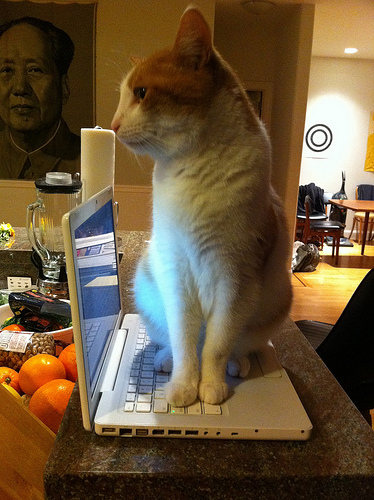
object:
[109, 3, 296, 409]
cat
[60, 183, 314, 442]
laptop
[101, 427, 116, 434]
port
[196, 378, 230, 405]
paw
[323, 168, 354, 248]
vacuum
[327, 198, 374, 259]
dining room table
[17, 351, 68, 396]
orange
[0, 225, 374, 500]
counter top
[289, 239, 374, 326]
floor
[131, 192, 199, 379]
reflection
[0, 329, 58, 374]
bag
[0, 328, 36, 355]
label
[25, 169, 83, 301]
blender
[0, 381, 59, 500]
basket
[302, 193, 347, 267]
chair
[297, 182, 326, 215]
jacket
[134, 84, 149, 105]
eye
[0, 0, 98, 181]
portrait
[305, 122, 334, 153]
target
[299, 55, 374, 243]
wall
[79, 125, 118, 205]
paper towels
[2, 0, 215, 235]
wall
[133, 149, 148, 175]
whiskers